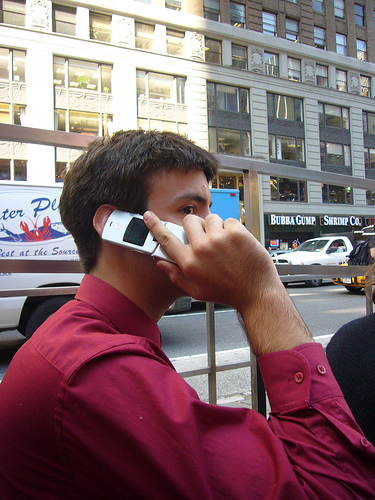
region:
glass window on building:
[206, 78, 214, 109]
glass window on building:
[214, 83, 237, 111]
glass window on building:
[237, 88, 246, 113]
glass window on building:
[266, 93, 272, 116]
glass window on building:
[273, 95, 293, 120]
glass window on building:
[293, 97, 302, 123]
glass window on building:
[207, 125, 215, 151]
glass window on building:
[218, 127, 239, 155]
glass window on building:
[241, 130, 250, 155]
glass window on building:
[275, 178, 298, 202]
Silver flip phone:
[93, 197, 217, 299]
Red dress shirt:
[8, 265, 371, 499]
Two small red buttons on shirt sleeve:
[294, 357, 332, 390]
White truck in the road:
[263, 220, 364, 313]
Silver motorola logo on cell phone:
[108, 222, 120, 233]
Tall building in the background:
[1, 1, 374, 249]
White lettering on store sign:
[265, 211, 366, 232]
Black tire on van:
[17, 278, 90, 365]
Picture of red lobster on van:
[17, 209, 57, 250]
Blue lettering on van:
[1, 195, 88, 268]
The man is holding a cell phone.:
[0, 120, 373, 498]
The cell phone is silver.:
[99, 196, 233, 290]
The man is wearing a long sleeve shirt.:
[0, 127, 374, 498]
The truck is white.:
[265, 233, 374, 295]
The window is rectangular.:
[50, 50, 121, 101]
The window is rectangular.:
[132, 62, 194, 102]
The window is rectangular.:
[201, 76, 258, 119]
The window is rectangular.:
[263, 87, 308, 128]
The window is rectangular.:
[315, 97, 356, 131]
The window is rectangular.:
[310, 136, 356, 174]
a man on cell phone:
[39, 136, 287, 309]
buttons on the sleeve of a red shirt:
[247, 346, 346, 416]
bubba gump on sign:
[257, 202, 362, 239]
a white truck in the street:
[276, 233, 364, 290]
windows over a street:
[207, 98, 374, 183]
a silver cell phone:
[109, 207, 185, 268]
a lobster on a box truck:
[13, 206, 53, 249]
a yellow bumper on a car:
[335, 250, 374, 291]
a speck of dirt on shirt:
[129, 400, 153, 425]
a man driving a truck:
[328, 238, 345, 258]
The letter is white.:
[266, 210, 276, 227]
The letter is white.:
[275, 214, 281, 226]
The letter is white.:
[279, 213, 286, 226]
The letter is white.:
[284, 212, 290, 224]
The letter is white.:
[289, 213, 295, 224]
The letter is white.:
[294, 210, 302, 225]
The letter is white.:
[300, 214, 306, 225]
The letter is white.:
[303, 211, 312, 226]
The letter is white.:
[310, 209, 317, 225]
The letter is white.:
[321, 210, 329, 226]